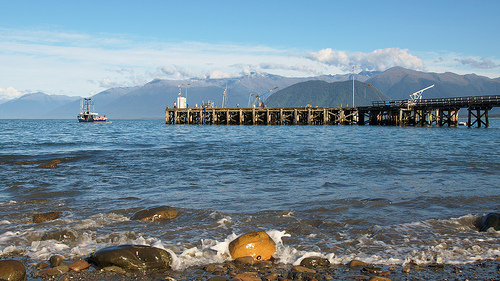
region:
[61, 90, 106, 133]
that is a ship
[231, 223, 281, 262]
that is a stone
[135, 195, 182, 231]
that is a stone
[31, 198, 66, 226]
that is a stone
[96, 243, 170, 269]
that is a stone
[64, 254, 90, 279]
that is a stone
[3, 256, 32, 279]
that is a stone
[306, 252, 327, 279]
that is a stone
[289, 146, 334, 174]
those are cool waters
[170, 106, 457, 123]
that is a bridge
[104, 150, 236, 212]
a body of water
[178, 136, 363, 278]
a body of water that is blue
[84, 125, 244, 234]
a body of water with waves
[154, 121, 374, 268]
a body of water that is choppy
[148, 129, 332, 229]
a body of wavy water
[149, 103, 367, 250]
a body of choppy water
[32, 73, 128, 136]
a boat in the water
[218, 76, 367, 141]
a peir in the water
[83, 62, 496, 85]
A range of mountains.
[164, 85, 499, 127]
A dock in the ocean.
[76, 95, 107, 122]
A boat coming in from the ocean.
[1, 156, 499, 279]
A very rocky shore line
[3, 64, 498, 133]
A dock with a mountain range in the background.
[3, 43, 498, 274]
A shoreline with a dock and mountain range in the background.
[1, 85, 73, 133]
A mountain with an ocean in the foreground.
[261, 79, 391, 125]
A mountain behind a dock.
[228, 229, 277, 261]
A tan rock in the ocean shore.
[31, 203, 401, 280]
A tide coming in over some rocks.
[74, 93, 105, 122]
a boat floating away in the water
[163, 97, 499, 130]
a long pier above the water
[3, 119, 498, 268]
the ocean surrounding the pier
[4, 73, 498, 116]
the hills in the background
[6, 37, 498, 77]
the white clouds in the sky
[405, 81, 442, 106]
a cran sitting on the pier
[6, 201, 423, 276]
some stones in the water and the beach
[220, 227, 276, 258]
a metal object next to the rocks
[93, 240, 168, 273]
a big rock on the beach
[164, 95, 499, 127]
A wooden bridge above water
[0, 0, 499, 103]
A cloudy blue sky above.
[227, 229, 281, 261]
A large orange rock.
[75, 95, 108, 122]
A boat in a distance.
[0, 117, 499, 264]
A body of water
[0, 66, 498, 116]
Mountains in the distance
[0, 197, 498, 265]
Waves hitting the shore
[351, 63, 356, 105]
A tall metal pole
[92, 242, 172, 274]
A large dark rock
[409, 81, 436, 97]
A white crane.